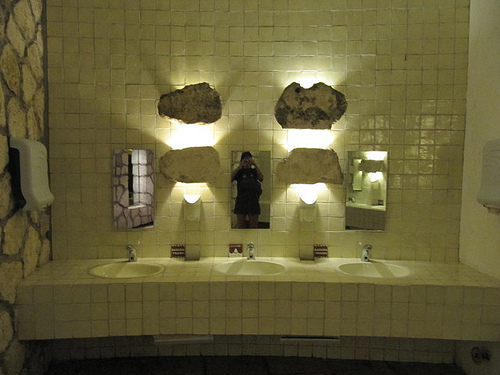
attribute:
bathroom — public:
[0, 1, 499, 372]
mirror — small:
[225, 144, 277, 235]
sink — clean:
[332, 240, 414, 282]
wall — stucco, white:
[451, 1, 500, 374]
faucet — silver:
[352, 238, 380, 266]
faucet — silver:
[239, 236, 264, 264]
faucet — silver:
[120, 237, 143, 265]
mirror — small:
[344, 147, 396, 236]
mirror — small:
[104, 144, 162, 237]